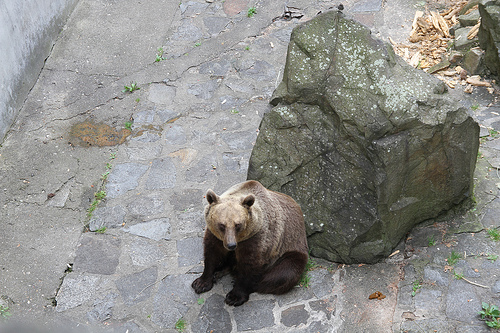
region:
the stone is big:
[322, 203, 336, 228]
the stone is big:
[327, 235, 343, 240]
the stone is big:
[314, 229, 339, 251]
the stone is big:
[357, 231, 372, 246]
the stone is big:
[340, 229, 368, 264]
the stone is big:
[339, 227, 354, 247]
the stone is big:
[344, 229, 359, 249]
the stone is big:
[382, 214, 395, 230]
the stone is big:
[353, 233, 368, 250]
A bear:
[214, 179, 300, 330]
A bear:
[230, 168, 267, 231]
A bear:
[190, 167, 256, 291]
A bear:
[217, 236, 262, 316]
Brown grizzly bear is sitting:
[199, 189, 314, 298]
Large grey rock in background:
[276, 22, 477, 264]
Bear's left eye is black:
[217, 218, 224, 232]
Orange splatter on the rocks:
[71, 116, 128, 148]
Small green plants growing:
[438, 242, 465, 270]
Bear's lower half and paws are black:
[191, 242, 304, 296]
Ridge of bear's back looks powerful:
[236, 178, 296, 210]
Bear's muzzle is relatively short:
[221, 233, 243, 252]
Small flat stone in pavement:
[143, 86, 175, 105]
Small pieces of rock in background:
[409, 13, 459, 69]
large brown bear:
[182, 157, 317, 312]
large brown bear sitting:
[159, 131, 341, 311]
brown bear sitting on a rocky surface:
[178, 161, 328, 331]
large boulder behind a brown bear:
[166, 18, 391, 300]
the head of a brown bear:
[191, 178, 259, 260]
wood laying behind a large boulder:
[396, 1, 492, 162]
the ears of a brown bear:
[189, 179, 279, 214]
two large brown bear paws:
[178, 273, 275, 320]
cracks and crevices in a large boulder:
[308, 37, 433, 265]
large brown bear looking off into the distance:
[164, 141, 321, 328]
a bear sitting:
[171, 161, 323, 316]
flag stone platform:
[127, 89, 226, 166]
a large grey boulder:
[232, 16, 480, 261]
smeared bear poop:
[60, 111, 188, 163]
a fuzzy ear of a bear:
[235, 190, 263, 212]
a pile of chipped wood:
[399, 10, 459, 70]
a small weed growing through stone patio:
[463, 292, 499, 323]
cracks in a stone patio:
[63, 55, 213, 92]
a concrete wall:
[3, 12, 60, 84]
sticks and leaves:
[420, 238, 485, 303]